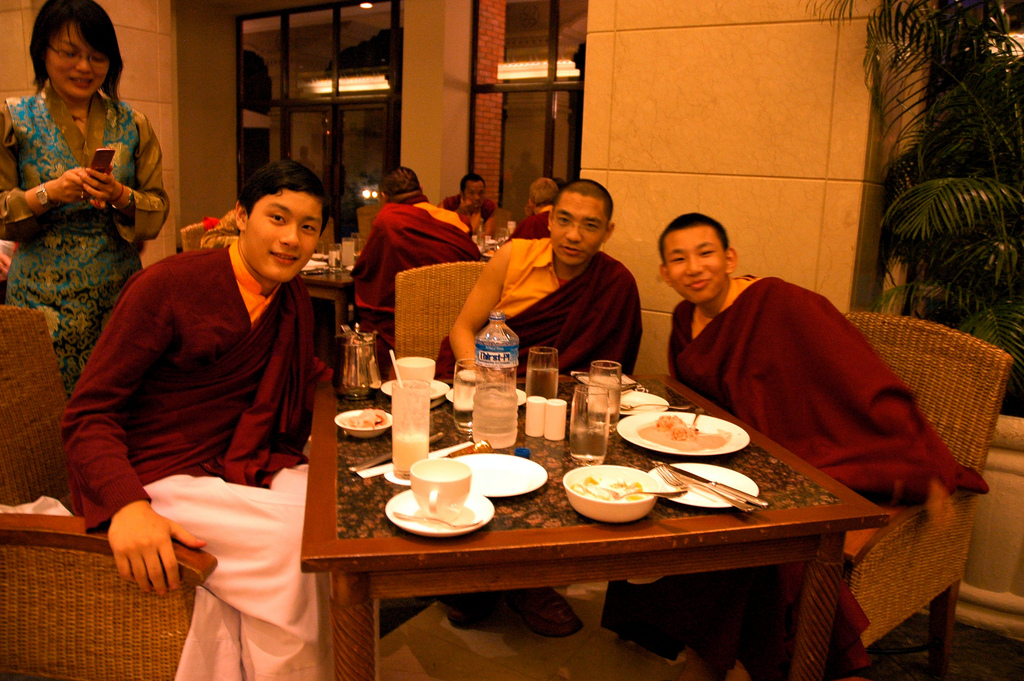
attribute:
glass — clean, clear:
[285, 8, 336, 94]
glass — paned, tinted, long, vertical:
[289, 13, 331, 93]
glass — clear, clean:
[239, 17, 279, 98]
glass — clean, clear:
[235, 105, 281, 198]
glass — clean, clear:
[286, 112, 321, 196]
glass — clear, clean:
[339, 102, 388, 227]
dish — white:
[383, 487, 492, 536]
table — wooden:
[298, 370, 887, 678]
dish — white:
[419, 447, 546, 498]